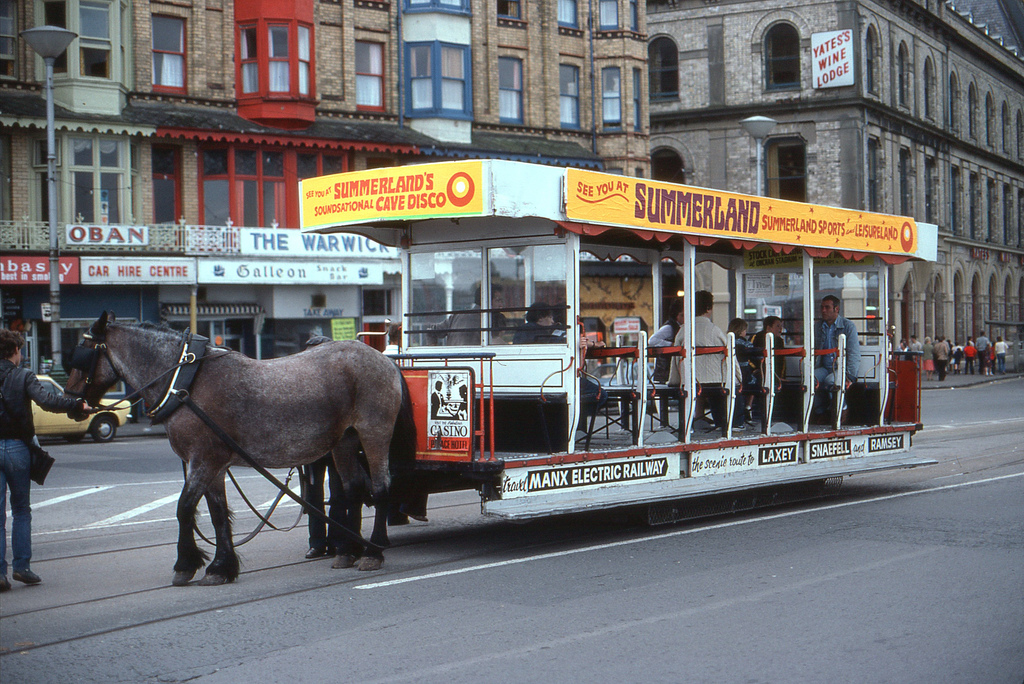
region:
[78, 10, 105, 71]
a window on a building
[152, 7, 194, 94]
a window on a building a window on a building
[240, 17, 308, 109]
a window on a building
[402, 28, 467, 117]
a window on a building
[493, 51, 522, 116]
a window on a building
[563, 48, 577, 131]
a window on a building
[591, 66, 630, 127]
a window on a building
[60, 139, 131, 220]
a window on a building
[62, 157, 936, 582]
A horse drawn trolley.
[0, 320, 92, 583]
Man leading the horse.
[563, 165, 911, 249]
The yellow sign on top side of trolley.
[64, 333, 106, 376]
The blinders on the horse.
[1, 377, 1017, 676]
The street the trolley is on.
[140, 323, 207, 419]
The harness on the horse.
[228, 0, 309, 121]
Red trimmed second story window.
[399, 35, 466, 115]
A blue trimmed second story window.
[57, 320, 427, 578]
a brown and black horse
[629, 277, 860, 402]
people sitting on the trolley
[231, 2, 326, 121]
a red trimmed window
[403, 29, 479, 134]
a blue trimmed window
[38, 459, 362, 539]
white lines on the road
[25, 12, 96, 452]
a tall lamp post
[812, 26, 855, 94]
a red and white sign on side of building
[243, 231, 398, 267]
a blue and white sign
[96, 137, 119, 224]
building has a window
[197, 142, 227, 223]
building has a window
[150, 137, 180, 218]
building has a window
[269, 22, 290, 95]
building has a window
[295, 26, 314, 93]
building has a window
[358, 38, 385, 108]
building has a window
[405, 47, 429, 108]
building has a window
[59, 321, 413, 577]
horse is color black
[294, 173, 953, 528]
white and red tramway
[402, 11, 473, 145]
blue and white window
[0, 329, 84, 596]
man is holding the horse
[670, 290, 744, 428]
woman is sitting in the tramway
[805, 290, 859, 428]
man is sitting in the tramway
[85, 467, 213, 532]
white line on the road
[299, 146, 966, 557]
tramway is on the road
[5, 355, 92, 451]
man is wearing a black jacket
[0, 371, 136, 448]
car is color yellow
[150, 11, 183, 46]
glass is clear and clean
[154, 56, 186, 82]
glass is clear and clean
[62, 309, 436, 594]
Brown horse with grey in it.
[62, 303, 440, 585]
A horse pulling a trolly.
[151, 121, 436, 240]
A group of red windows on the building.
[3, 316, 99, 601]
A person wearing a jacket guiding the horse.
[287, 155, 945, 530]
People sitting on a trolly.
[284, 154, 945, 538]
A trolley that is being pulled by a horse.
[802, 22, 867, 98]
A sign on the back building that says Yates's Wine Lodge.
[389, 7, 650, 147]
A group of blue windows on the building.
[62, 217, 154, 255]
A red sign that says OBAN.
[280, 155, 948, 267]
Yellow signs on the top portion of the trolley.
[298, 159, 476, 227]
the sign is yellow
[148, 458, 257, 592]
Legs of a horse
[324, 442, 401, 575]
Legs of a horse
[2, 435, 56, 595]
Jeans on a man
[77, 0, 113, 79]
window on large apartment building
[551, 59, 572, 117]
window on large apartment building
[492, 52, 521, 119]
window on large apartment building